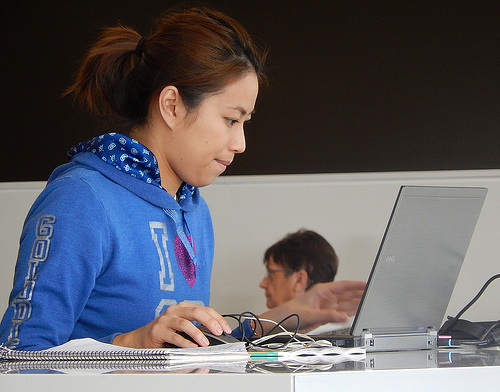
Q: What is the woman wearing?
A: Sweatshirt.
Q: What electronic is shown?
A: Laptop.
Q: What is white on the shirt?
A: Letters.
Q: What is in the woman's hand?
A: Mouse.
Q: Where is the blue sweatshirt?
A: On nearest girl.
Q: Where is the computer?
A: On desk.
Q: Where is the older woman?
A: Background.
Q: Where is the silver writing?
A: On sweatshirt.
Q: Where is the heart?
A: Next to 'I'.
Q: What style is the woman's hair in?
A: Pony tail.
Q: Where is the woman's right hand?
A: On mouse.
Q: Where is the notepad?
A: Next to mouse.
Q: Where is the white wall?
A: Beyond the women.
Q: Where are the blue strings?
A: On sweatshirt.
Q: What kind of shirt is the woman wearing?
A: A blue hoodie.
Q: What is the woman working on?
A: A laptop.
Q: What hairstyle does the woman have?
A: A ponytail.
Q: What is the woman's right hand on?
A: A mouse.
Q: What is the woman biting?
A: Her lower lip.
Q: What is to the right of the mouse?
A: A spiral notebook.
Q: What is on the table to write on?
A: A notebook.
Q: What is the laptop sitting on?
A: A desk.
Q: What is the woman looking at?
A: A laptop.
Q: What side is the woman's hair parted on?
A: The right.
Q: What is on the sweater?
A: Words.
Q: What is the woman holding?
A: A mouse.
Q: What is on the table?
A: A laptop.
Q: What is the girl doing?
A: Using a laptop.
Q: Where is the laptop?
A: On the table.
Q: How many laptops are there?
A: One.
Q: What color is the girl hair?
A: Brown.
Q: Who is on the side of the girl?
A: An older lady.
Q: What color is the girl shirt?
A: Blue.